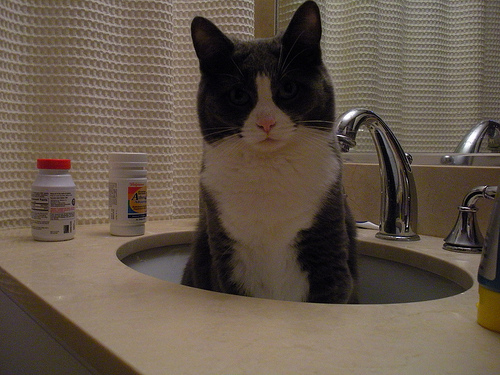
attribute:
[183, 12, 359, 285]
cat — gray, white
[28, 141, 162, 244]
bottles — white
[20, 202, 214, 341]
counter — clean, clearn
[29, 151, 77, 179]
lid — red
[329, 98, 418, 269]
faucet — silver, shiny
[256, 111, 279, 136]
nose — pink